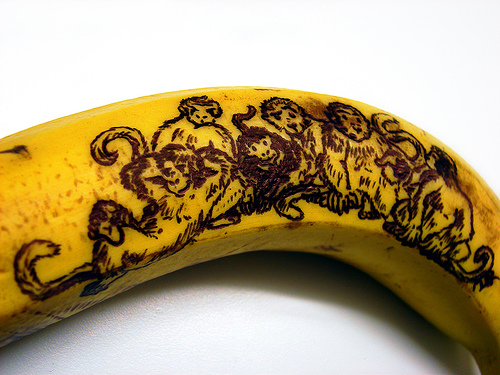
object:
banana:
[0, 82, 497, 375]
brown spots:
[0, 144, 29, 158]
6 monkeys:
[386, 143, 499, 286]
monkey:
[14, 148, 236, 301]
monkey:
[153, 94, 236, 159]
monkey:
[230, 106, 309, 216]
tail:
[13, 235, 85, 304]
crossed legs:
[84, 196, 138, 265]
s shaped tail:
[231, 104, 258, 126]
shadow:
[257, 259, 327, 300]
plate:
[81, 291, 394, 375]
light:
[223, 324, 247, 344]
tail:
[371, 112, 422, 152]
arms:
[266, 153, 305, 195]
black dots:
[252, 146, 257, 151]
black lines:
[180, 201, 185, 213]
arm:
[118, 151, 165, 199]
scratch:
[36, 312, 62, 320]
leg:
[84, 199, 140, 247]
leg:
[88, 242, 117, 291]